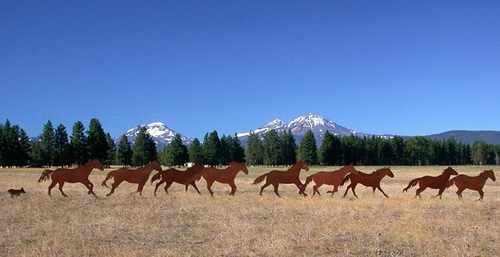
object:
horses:
[402, 166, 459, 199]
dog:
[6, 187, 27, 198]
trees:
[295, 127, 318, 169]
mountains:
[105, 118, 201, 149]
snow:
[125, 119, 173, 132]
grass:
[0, 163, 500, 256]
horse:
[38, 158, 104, 199]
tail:
[36, 170, 54, 183]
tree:
[189, 137, 204, 166]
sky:
[0, 0, 500, 141]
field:
[0, 117, 499, 256]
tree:
[88, 118, 111, 168]